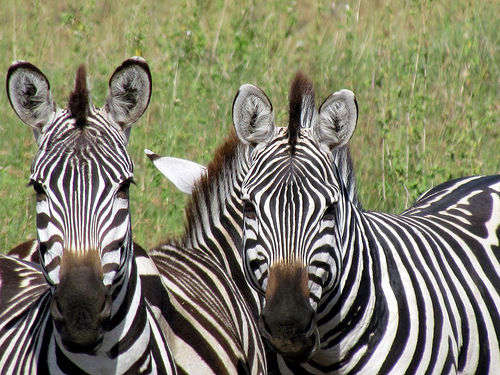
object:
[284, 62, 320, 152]
mane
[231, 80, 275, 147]
ear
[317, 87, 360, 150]
ear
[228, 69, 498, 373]
zebra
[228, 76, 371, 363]
head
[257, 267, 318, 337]
nose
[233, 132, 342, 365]
face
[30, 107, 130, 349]
face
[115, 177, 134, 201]
eye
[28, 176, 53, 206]
eye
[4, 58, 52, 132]
ear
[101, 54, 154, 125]
ear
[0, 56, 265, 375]
zebra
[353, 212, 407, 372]
stripe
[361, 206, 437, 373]
stripe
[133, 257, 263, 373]
stripe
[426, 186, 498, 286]
stripe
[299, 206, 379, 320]
stripe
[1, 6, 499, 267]
grass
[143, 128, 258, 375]
zebras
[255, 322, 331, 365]
mouth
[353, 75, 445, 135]
field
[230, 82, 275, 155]
ear